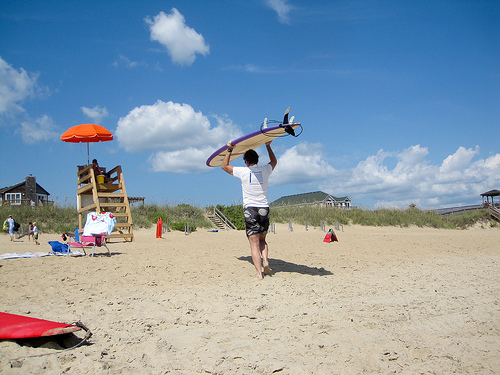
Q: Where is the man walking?
A: On the beach.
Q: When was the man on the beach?
A: During daylight hours.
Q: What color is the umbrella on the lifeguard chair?
A: Orange.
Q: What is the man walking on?
A: Sand.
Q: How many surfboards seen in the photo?
A: Two.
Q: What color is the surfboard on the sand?
A: Red.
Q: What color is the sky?
A: Blue and white.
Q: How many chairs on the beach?
A: 2.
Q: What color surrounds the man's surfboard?
A: Purple.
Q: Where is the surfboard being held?
A: Over the man's head.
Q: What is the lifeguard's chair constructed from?
A: Wood.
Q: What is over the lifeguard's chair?
A: An umbrella.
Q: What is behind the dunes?
A: Houses.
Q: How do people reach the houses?
A: Stairs.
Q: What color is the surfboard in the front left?
A: Red.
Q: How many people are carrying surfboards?
A: 1.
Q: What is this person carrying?
A: A surfboard.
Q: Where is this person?
A: On a beach.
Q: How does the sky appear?
A: Partly cloudy.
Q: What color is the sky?
A: Blue.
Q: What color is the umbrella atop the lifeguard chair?
A: Orange.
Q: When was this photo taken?
A: In the daytime.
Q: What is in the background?
A: Houses.